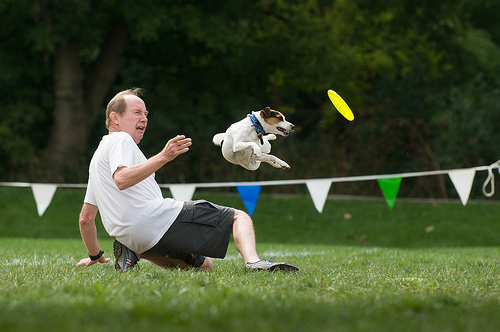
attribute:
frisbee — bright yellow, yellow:
[327, 90, 358, 122]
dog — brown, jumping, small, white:
[213, 106, 295, 171]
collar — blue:
[247, 109, 267, 140]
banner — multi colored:
[249, 170, 498, 217]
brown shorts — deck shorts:
[158, 197, 234, 260]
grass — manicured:
[300, 202, 498, 331]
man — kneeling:
[78, 89, 300, 275]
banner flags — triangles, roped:
[291, 158, 500, 226]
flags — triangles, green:
[377, 176, 403, 211]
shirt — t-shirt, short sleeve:
[86, 132, 184, 253]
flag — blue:
[237, 185, 262, 215]